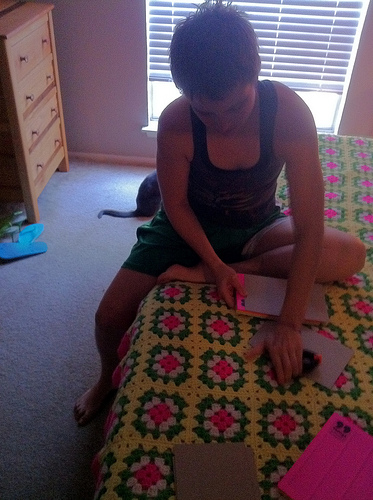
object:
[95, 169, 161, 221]
cat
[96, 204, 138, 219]
tail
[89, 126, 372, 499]
blanket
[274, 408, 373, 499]
paper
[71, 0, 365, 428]
boy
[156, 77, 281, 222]
tank top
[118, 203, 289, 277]
shorts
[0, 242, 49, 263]
flip flops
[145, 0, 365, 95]
blind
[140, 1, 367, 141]
window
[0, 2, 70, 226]
dresser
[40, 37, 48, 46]
knob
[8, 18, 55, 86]
drawer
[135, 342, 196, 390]
square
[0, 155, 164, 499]
floor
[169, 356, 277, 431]
stuff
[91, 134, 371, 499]
bed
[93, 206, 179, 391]
leg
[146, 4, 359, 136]
glare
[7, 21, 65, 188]
four drawers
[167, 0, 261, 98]
short hair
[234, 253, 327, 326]
tablet of paper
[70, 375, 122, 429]
right foot